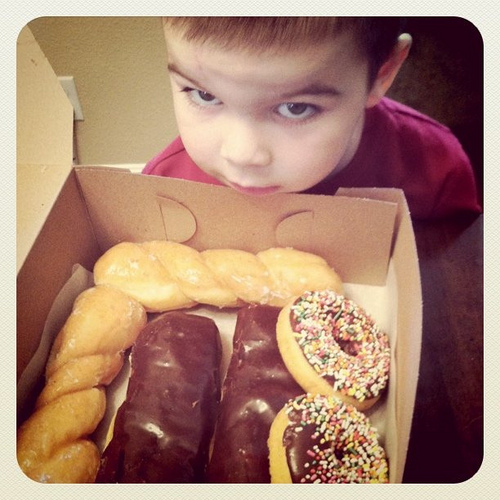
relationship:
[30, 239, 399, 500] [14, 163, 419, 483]
donuts in box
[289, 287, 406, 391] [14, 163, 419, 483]
sprinkles in box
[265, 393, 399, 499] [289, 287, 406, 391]
donuts with sprinkles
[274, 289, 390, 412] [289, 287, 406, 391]
donut has frosting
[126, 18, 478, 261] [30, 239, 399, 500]
kid nex to donut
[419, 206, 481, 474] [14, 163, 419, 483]
table next to box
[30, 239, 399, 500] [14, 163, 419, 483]
donuts in a box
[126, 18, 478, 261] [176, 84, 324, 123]
kid seen eyes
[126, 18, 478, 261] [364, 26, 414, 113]
kid seen ear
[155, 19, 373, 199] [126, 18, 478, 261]
face of boy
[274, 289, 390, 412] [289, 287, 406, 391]
donut with sprinkles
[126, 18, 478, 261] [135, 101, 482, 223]
child with red shirt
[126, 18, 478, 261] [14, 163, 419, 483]
child holding box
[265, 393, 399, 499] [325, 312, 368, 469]
donuts with hole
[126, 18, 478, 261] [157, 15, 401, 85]
child has brown hair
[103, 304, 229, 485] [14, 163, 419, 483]
donut in box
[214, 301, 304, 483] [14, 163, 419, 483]
eclair in box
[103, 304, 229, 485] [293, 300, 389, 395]
donut with chocolate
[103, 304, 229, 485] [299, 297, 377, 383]
donut with sprinkles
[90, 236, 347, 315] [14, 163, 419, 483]
pastry in box